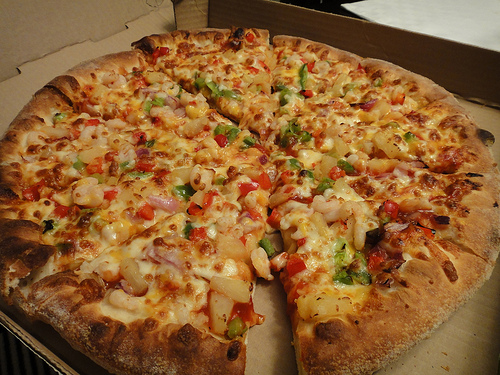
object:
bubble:
[312, 319, 348, 344]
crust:
[294, 238, 489, 373]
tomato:
[136, 203, 157, 222]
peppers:
[194, 75, 221, 96]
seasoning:
[92, 47, 423, 311]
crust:
[468, 118, 498, 244]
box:
[0, 0, 500, 375]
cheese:
[312, 191, 354, 223]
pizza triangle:
[271, 170, 493, 375]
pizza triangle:
[273, 95, 498, 174]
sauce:
[227, 301, 262, 331]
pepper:
[333, 243, 371, 284]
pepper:
[299, 62, 309, 90]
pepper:
[215, 122, 256, 144]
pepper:
[334, 157, 357, 173]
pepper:
[170, 183, 194, 203]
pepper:
[259, 237, 277, 256]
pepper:
[227, 315, 244, 337]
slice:
[254, 161, 479, 369]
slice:
[131, 25, 299, 148]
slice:
[267, 29, 372, 144]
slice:
[0, 89, 268, 219]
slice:
[7, 161, 281, 369]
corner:
[174, 2, 211, 30]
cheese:
[146, 254, 220, 325]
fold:
[2, 5, 198, 86]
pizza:
[7, 27, 498, 375]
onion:
[82, 179, 147, 286]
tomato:
[240, 174, 272, 195]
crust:
[0, 214, 55, 286]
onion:
[373, 156, 430, 176]